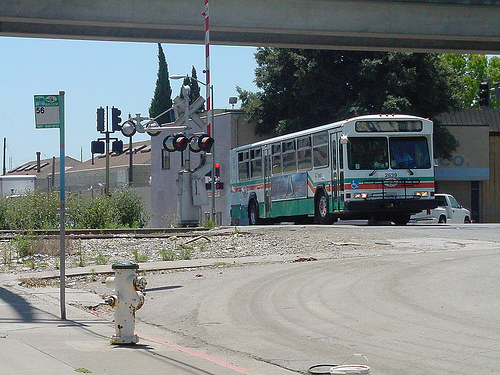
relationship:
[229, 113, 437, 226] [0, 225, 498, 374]
bus on road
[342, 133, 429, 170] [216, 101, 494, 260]
windshield on bus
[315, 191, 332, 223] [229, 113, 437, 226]
front wheel on bus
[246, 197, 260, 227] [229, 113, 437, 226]
wheel on bus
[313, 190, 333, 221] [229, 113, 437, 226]
wheel on bus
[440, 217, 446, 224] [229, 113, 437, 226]
wheel on bus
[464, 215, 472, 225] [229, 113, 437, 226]
wheel on bus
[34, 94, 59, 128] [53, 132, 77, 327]
sign on pole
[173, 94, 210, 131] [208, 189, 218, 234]
sign on pole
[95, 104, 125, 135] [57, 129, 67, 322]
traffic signals on pole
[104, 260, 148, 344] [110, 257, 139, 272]
fire hydrant with cap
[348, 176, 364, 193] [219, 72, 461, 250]
handicap emblem on front of bus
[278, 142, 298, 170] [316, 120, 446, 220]
window on bus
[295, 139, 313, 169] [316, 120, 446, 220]
window on bus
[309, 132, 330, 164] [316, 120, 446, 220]
window on bus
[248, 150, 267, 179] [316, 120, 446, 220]
window on bus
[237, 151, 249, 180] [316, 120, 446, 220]
window on bus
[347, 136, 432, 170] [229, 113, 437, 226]
windshield of bus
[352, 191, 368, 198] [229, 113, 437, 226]
headlights on front of bus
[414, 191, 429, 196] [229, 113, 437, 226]
headlights on front of bus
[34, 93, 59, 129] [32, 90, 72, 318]
sign on pole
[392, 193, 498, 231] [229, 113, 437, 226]
white pickup behind bus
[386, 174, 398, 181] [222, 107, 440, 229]
number on bus